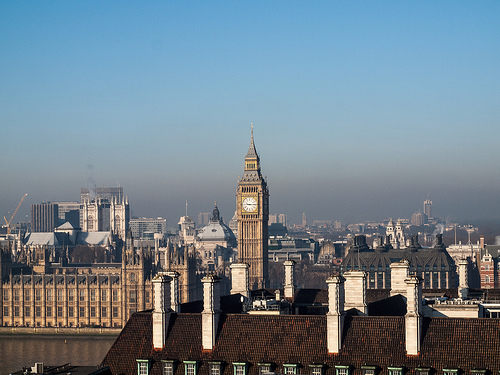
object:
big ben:
[236, 122, 271, 294]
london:
[0, 113, 498, 375]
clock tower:
[238, 121, 270, 292]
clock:
[241, 196, 258, 214]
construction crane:
[0, 193, 29, 234]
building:
[0, 186, 103, 334]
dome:
[194, 200, 237, 239]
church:
[194, 201, 238, 292]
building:
[344, 216, 472, 259]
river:
[0, 331, 107, 362]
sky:
[14, 96, 472, 143]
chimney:
[343, 271, 369, 316]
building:
[94, 259, 500, 375]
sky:
[1, 5, 496, 62]